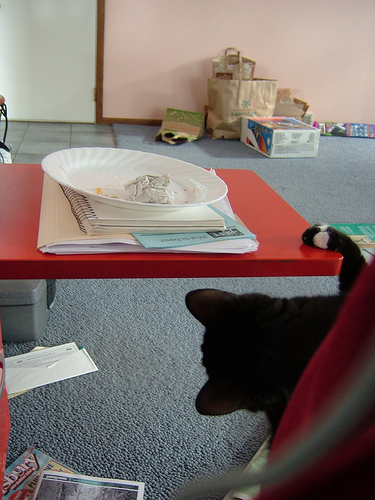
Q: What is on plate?
A: Crumpled napkins.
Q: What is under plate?
A: Spiral notebook.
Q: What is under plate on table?
A: Folder with papers under notebook.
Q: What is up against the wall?
A: Brown carry bags.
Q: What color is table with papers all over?
A: Orange.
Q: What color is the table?
A: Red.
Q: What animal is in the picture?
A: Cat.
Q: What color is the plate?
A: White.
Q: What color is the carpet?
A: Blue.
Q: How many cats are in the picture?
A: 1.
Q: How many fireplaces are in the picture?
A: None.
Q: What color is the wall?
A: Pink.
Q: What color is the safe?
A: Grey.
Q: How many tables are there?
A: 1.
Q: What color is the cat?
A: Black.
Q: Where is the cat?
A: Under the desk.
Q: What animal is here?
A: Cat.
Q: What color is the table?
A: Red.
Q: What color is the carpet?
A: Gray.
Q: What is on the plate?
A: Used napkin and crumbs.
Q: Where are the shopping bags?
A: Against the wall.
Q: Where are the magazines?
A: Under the desk.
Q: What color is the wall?
A: Pink.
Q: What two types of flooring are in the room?
A: Carpet and tile.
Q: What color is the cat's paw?
A: Black and white.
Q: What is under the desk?
A: A cat is leaning sideways under the desk.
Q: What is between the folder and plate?
A: There is a notebook between the folder and plate.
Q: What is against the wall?
A: There is a box and shopping bags against the wall.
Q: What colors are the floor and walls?
A: The walls are pink and white with brown trim, and the floor is grey.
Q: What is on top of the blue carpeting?
A: There are magazines on top of the blue carpeting.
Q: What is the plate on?
A: Books.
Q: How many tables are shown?
A: One.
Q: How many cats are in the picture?
A: One.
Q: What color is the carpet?
A: Grey.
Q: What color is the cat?
A: Black.